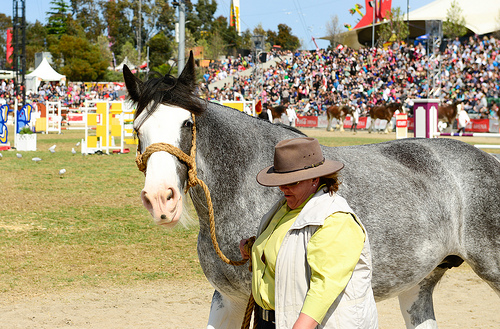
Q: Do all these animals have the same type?
A: No, there are both horses and pigeons.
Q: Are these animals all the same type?
A: No, there are both horses and pigeons.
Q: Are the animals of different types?
A: Yes, they are horses and pigeons.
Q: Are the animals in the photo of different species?
A: Yes, they are horses and pigeons.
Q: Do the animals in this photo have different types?
A: Yes, they are horses and pigeons.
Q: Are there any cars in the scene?
A: No, there are no cars.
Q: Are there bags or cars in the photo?
A: No, there are no cars or bags.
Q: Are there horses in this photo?
A: Yes, there is a horse.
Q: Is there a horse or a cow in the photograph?
A: Yes, there is a horse.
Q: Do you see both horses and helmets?
A: No, there is a horse but no helmets.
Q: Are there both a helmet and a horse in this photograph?
A: No, there is a horse but no helmets.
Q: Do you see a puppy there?
A: No, there are no puppys.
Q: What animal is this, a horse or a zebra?
A: This is a horse.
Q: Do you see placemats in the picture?
A: No, there are no placemats.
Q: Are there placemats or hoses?
A: No, there are no placemats or hoses.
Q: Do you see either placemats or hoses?
A: No, there are no placemats or hoses.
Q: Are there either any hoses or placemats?
A: No, there are no placemats or hoses.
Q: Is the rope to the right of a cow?
A: No, the rope is to the right of a pigeon.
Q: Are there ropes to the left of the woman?
A: Yes, there is a rope to the left of the woman.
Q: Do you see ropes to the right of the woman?
A: No, the rope is to the left of the woman.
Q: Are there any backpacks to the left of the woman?
A: No, there is a rope to the left of the woman.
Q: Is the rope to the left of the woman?
A: Yes, the rope is to the left of the woman.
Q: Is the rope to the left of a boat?
A: No, the rope is to the left of the woman.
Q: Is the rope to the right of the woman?
A: No, the rope is to the left of the woman.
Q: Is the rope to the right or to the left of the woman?
A: The rope is to the left of the woman.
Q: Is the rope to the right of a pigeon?
A: Yes, the rope is to the right of a pigeon.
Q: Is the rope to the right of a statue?
A: No, the rope is to the right of a pigeon.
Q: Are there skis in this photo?
A: No, there are no skis.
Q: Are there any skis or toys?
A: No, there are no skis or toys.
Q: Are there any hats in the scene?
A: Yes, there is a hat.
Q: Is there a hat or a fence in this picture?
A: Yes, there is a hat.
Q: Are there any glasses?
A: No, there are no glasses.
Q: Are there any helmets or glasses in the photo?
A: No, there are no glasses or helmets.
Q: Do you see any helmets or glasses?
A: No, there are no glasses or helmets.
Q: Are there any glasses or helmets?
A: No, there are no glasses or helmets.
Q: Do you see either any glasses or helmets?
A: No, there are no glasses or helmets.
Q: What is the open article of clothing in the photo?
A: The clothing item is a vest.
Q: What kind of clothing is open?
A: The clothing is a vest.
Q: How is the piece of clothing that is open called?
A: The clothing item is a vest.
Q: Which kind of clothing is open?
A: The clothing is a vest.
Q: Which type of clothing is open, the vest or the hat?
A: The vest is open.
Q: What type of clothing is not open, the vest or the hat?
A: The hat is not open.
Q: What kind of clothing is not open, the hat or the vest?
A: The hat is not open.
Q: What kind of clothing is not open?
A: The clothing is a hat.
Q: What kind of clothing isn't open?
A: The clothing is a hat.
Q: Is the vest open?
A: Yes, the vest is open.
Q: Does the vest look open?
A: Yes, the vest is open.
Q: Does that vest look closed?
A: No, the vest is open.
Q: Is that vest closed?
A: No, the vest is open.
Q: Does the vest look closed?
A: No, the vest is open.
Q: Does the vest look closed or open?
A: The vest is open.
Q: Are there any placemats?
A: No, there are no placemats.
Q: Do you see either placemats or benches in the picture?
A: No, there are no placemats or benches.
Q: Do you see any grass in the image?
A: Yes, there is grass.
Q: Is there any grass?
A: Yes, there is grass.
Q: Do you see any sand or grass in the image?
A: Yes, there is grass.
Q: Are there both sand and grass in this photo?
A: Yes, there are both grass and sand.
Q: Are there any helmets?
A: No, there are no helmets.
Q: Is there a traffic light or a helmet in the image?
A: No, there are no helmets or traffic lights.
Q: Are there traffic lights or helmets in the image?
A: No, there are no helmets or traffic lights.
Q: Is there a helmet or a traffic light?
A: No, there are no helmets or traffic lights.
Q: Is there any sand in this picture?
A: Yes, there is sand.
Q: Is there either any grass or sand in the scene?
A: Yes, there is sand.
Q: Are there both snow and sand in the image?
A: No, there is sand but no snow.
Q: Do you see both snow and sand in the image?
A: No, there is sand but no snow.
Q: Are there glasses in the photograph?
A: No, there are no glasses.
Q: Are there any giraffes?
A: No, there are no giraffes.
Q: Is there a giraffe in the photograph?
A: No, there are no giraffes.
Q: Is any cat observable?
A: No, there are no cats.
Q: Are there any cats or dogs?
A: No, there are no cats or dogs.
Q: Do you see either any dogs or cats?
A: No, there are no cats or dogs.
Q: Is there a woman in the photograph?
A: Yes, there is a woman.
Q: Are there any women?
A: Yes, there is a woman.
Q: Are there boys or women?
A: Yes, there is a woman.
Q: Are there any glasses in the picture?
A: No, there are no glasses.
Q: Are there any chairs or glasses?
A: No, there are no glasses or chairs.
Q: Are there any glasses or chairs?
A: No, there are no glasses or chairs.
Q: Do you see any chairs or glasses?
A: No, there are no glasses or chairs.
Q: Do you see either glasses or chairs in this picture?
A: No, there are no glasses or chairs.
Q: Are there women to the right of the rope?
A: Yes, there is a woman to the right of the rope.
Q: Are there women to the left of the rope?
A: No, the woman is to the right of the rope.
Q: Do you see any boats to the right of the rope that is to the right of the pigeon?
A: No, there is a woman to the right of the rope.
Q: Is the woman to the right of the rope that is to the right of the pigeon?
A: Yes, the woman is to the right of the rope.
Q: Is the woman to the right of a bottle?
A: No, the woman is to the right of the rope.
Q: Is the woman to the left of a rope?
A: No, the woman is to the right of a rope.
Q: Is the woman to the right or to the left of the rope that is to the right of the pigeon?
A: The woman is to the right of the rope.